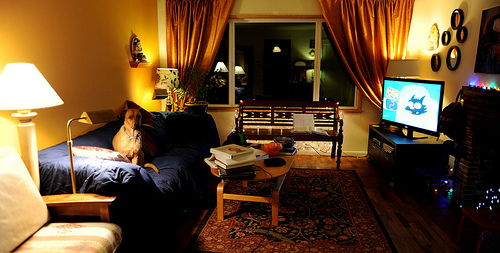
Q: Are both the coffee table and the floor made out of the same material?
A: Yes, both the coffee table and the floor are made of wood.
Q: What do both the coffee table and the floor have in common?
A: The material, both the coffee table and the floor are wooden.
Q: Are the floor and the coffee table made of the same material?
A: Yes, both the floor and the coffee table are made of wood.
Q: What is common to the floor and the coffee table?
A: The material, both the floor and the coffee table are wooden.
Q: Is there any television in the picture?
A: Yes, there is a television.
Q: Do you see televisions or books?
A: Yes, there is a television.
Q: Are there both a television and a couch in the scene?
A: Yes, there are both a television and a couch.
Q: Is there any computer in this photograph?
A: No, there are no computers.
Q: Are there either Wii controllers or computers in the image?
A: No, there are no computers or Wii controllers.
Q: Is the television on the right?
A: Yes, the television is on the right of the image.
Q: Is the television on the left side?
A: No, the television is on the right of the image.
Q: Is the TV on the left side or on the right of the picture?
A: The TV is on the right of the image.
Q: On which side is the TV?
A: The TV is on the right of the image.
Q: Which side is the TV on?
A: The TV is on the right of the image.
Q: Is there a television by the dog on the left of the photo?
A: Yes, there is a television by the dog.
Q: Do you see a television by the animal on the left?
A: Yes, there is a television by the dog.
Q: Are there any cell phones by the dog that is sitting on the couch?
A: No, there is a television by the dog.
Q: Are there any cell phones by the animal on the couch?
A: No, there is a television by the dog.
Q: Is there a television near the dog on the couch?
A: Yes, there is a television near the dog.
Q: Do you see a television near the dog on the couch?
A: Yes, there is a television near the dog.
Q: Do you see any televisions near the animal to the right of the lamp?
A: Yes, there is a television near the dog.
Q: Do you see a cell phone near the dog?
A: No, there is a television near the dog.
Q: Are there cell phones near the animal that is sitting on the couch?
A: No, there is a television near the dog.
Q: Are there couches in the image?
A: Yes, there is a couch.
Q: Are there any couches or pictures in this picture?
A: Yes, there is a couch.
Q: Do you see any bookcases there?
A: No, there are no bookcases.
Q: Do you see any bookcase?
A: No, there are no bookcases.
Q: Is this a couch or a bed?
A: This is a couch.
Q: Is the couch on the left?
A: Yes, the couch is on the left of the image.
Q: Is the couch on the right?
A: No, the couch is on the left of the image.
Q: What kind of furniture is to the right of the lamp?
A: The piece of furniture is a couch.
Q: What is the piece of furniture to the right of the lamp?
A: The piece of furniture is a couch.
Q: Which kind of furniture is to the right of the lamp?
A: The piece of furniture is a couch.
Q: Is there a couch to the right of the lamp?
A: Yes, there is a couch to the right of the lamp.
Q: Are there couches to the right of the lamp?
A: Yes, there is a couch to the right of the lamp.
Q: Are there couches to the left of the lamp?
A: No, the couch is to the right of the lamp.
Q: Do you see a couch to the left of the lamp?
A: No, the couch is to the right of the lamp.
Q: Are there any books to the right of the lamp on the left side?
A: No, there is a couch to the right of the lamp.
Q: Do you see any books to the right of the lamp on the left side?
A: No, there is a couch to the right of the lamp.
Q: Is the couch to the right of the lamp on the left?
A: Yes, the couch is to the right of the lamp.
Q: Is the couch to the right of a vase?
A: No, the couch is to the right of the lamp.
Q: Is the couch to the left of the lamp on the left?
A: No, the couch is to the right of the lamp.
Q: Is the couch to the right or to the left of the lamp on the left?
A: The couch is to the right of the lamp.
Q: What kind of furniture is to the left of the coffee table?
A: The piece of furniture is a couch.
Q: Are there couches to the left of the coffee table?
A: Yes, there is a couch to the left of the coffee table.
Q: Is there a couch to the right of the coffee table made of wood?
A: No, the couch is to the left of the coffee table.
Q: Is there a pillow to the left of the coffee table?
A: No, there is a couch to the left of the coffee table.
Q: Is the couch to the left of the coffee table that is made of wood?
A: Yes, the couch is to the left of the coffee table.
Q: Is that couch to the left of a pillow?
A: No, the couch is to the left of the coffee table.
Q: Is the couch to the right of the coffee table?
A: No, the couch is to the left of the coffee table.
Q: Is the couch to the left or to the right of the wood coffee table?
A: The couch is to the left of the coffee table.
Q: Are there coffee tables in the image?
A: Yes, there is a coffee table.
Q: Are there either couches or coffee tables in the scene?
A: Yes, there is a coffee table.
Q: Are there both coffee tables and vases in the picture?
A: No, there is a coffee table but no vases.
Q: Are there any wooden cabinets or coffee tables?
A: Yes, there is a wood coffee table.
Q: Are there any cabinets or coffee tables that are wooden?
A: Yes, the coffee table is wooden.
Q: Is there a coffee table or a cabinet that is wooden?
A: Yes, the coffee table is wooden.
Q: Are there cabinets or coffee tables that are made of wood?
A: Yes, the coffee table is made of wood.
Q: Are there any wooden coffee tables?
A: Yes, there is a wood coffee table.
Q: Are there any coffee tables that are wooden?
A: Yes, there is a coffee table that is wooden.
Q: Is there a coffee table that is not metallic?
A: Yes, there is a wooden coffee table.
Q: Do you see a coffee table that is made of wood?
A: Yes, there is a coffee table that is made of wood.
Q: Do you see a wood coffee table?
A: Yes, there is a coffee table that is made of wood.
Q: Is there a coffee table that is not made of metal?
A: Yes, there is a coffee table that is made of wood.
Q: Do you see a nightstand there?
A: No, there are no nightstands.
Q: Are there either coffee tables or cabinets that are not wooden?
A: No, there is a coffee table but it is wooden.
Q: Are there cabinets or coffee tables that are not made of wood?
A: No, there is a coffee table but it is made of wood.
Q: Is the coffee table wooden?
A: Yes, the coffee table is wooden.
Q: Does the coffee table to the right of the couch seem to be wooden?
A: Yes, the coffee table is wooden.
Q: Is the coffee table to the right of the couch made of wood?
A: Yes, the coffee table is made of wood.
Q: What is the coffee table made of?
A: The coffee table is made of wood.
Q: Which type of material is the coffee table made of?
A: The coffee table is made of wood.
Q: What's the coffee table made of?
A: The coffee table is made of wood.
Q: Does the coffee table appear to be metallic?
A: No, the coffee table is wooden.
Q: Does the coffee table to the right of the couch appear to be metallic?
A: No, the coffee table is wooden.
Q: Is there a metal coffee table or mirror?
A: No, there is a coffee table but it is wooden.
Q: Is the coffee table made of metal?
A: No, the coffee table is made of wood.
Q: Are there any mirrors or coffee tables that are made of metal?
A: No, there is a coffee table but it is made of wood.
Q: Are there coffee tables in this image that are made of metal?
A: No, there is a coffee table but it is made of wood.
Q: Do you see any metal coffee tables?
A: No, there is a coffee table but it is made of wood.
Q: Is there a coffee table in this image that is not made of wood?
A: No, there is a coffee table but it is made of wood.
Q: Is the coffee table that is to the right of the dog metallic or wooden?
A: The coffee table is wooden.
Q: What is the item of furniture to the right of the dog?
A: The piece of furniture is a coffee table.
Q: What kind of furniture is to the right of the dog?
A: The piece of furniture is a coffee table.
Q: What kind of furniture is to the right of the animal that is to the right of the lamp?
A: The piece of furniture is a coffee table.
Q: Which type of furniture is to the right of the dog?
A: The piece of furniture is a coffee table.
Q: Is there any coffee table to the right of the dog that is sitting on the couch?
A: Yes, there is a coffee table to the right of the dog.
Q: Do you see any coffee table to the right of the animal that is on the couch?
A: Yes, there is a coffee table to the right of the dog.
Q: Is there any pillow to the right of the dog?
A: No, there is a coffee table to the right of the dog.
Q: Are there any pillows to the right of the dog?
A: No, there is a coffee table to the right of the dog.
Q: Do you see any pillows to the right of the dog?
A: No, there is a coffee table to the right of the dog.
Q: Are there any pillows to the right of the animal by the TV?
A: No, there is a coffee table to the right of the dog.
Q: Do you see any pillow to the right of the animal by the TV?
A: No, there is a coffee table to the right of the dog.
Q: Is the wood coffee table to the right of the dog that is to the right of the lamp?
A: Yes, the coffee table is to the right of the dog.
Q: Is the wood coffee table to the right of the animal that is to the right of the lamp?
A: Yes, the coffee table is to the right of the dog.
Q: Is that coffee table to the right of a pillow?
A: No, the coffee table is to the right of the dog.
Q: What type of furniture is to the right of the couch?
A: The piece of furniture is a coffee table.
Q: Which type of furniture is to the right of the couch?
A: The piece of furniture is a coffee table.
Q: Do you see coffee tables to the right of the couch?
A: Yes, there is a coffee table to the right of the couch.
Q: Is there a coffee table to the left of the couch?
A: No, the coffee table is to the right of the couch.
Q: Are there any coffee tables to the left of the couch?
A: No, the coffee table is to the right of the couch.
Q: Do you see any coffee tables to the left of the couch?
A: No, the coffee table is to the right of the couch.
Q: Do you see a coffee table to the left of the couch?
A: No, the coffee table is to the right of the couch.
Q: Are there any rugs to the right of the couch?
A: No, there is a coffee table to the right of the couch.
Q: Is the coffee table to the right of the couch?
A: Yes, the coffee table is to the right of the couch.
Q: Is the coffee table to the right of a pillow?
A: No, the coffee table is to the right of the couch.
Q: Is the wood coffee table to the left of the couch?
A: No, the coffee table is to the right of the couch.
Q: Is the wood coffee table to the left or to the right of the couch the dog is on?
A: The coffee table is to the right of the couch.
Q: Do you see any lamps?
A: Yes, there is a lamp.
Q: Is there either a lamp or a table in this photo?
A: Yes, there is a lamp.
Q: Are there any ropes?
A: No, there are no ropes.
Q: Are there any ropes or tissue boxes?
A: No, there are no ropes or tissue boxes.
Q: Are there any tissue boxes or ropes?
A: No, there are no ropes or tissue boxes.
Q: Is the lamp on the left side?
A: Yes, the lamp is on the left of the image.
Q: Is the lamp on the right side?
A: No, the lamp is on the left of the image.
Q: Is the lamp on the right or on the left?
A: The lamp is on the left of the image.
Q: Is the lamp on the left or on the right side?
A: The lamp is on the left of the image.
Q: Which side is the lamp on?
A: The lamp is on the left of the image.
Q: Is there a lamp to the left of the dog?
A: Yes, there is a lamp to the left of the dog.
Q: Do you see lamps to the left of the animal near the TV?
A: Yes, there is a lamp to the left of the dog.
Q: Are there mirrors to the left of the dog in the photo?
A: No, there is a lamp to the left of the dog.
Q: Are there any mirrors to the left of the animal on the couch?
A: No, there is a lamp to the left of the dog.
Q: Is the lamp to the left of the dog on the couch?
A: Yes, the lamp is to the left of the dog.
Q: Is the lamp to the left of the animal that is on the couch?
A: Yes, the lamp is to the left of the dog.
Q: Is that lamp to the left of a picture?
A: No, the lamp is to the left of the dog.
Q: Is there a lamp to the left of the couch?
A: Yes, there is a lamp to the left of the couch.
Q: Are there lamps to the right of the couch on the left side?
A: No, the lamp is to the left of the couch.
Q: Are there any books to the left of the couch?
A: No, there is a lamp to the left of the couch.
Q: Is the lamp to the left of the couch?
A: Yes, the lamp is to the left of the couch.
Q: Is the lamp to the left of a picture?
A: No, the lamp is to the left of the couch.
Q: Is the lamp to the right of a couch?
A: No, the lamp is to the left of a couch.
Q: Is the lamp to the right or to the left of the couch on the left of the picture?
A: The lamp is to the left of the couch.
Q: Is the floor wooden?
A: Yes, the floor is wooden.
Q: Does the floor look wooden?
A: Yes, the floor is wooden.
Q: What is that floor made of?
A: The floor is made of wood.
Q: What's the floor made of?
A: The floor is made of wood.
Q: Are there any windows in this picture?
A: Yes, there is a window.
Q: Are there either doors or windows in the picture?
A: Yes, there is a window.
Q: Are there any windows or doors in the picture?
A: Yes, there is a window.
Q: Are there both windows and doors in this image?
A: No, there is a window but no doors.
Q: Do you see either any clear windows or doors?
A: Yes, there is a clear window.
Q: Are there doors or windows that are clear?
A: Yes, the window is clear.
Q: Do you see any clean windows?
A: Yes, there is a clean window.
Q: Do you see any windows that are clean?
A: Yes, there is a window that is clean.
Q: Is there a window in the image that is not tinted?
A: Yes, there is a clean window.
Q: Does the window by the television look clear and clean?
A: Yes, the window is clear and clean.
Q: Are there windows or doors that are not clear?
A: No, there is a window but it is clear.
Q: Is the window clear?
A: Yes, the window is clear.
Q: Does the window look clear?
A: Yes, the window is clear.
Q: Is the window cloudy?
A: No, the window is clear.